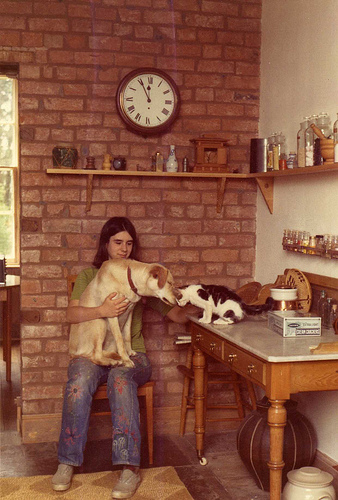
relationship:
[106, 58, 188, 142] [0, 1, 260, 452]
clock on wall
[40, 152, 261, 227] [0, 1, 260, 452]
shelf on wall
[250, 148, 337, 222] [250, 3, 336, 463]
shelf on wall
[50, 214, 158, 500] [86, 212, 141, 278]
girl has hair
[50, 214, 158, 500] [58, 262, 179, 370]
girl wears shirt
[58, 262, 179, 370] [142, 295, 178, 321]
shirt has sleeve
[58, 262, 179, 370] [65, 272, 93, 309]
shirt has sleeve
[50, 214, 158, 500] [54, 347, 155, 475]
girl wears jeans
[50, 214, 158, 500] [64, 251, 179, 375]
girl holds dog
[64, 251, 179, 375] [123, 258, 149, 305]
dog has collar